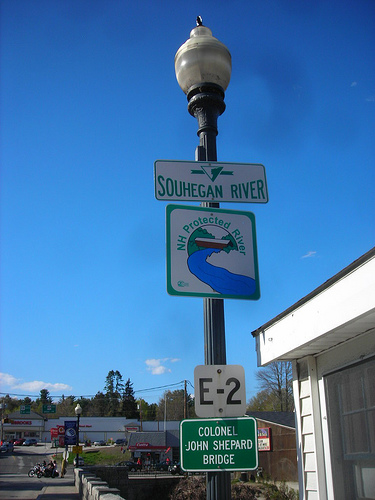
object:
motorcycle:
[30, 462, 45, 477]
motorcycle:
[38, 462, 59, 477]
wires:
[0, 379, 186, 397]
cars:
[0, 441, 15, 456]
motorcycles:
[29, 456, 61, 484]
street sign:
[193, 363, 246, 417]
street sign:
[72, 443, 84, 455]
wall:
[73, 469, 104, 497]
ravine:
[125, 475, 178, 499]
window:
[342, 408, 367, 453]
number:
[224, 375, 243, 408]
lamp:
[174, 14, 232, 94]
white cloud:
[296, 249, 319, 266]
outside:
[0, 362, 310, 500]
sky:
[0, 1, 372, 410]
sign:
[179, 418, 257, 471]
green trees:
[138, 397, 155, 419]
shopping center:
[0, 410, 126, 444]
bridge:
[127, 467, 184, 486]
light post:
[187, 83, 232, 498]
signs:
[154, 159, 268, 205]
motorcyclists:
[51, 458, 59, 479]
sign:
[165, 202, 260, 300]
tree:
[34, 387, 55, 420]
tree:
[120, 377, 139, 422]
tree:
[102, 368, 126, 414]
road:
[0, 439, 72, 499]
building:
[249, 248, 375, 499]